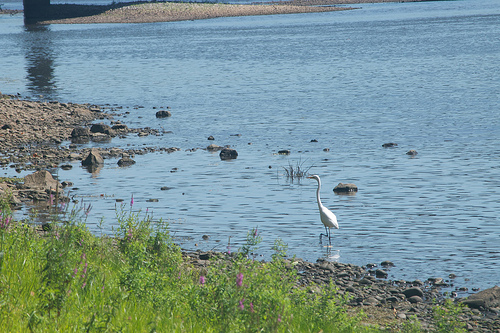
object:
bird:
[299, 174, 340, 244]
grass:
[2, 206, 467, 333]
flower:
[229, 269, 246, 289]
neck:
[316, 179, 323, 201]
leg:
[328, 227, 331, 239]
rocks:
[67, 124, 92, 145]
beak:
[305, 175, 314, 179]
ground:
[37, 0, 365, 26]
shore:
[321, 260, 434, 311]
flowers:
[194, 271, 210, 286]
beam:
[22, 21, 77, 31]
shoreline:
[12, 73, 274, 233]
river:
[0, 0, 500, 289]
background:
[193, 4, 459, 77]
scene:
[0, 0, 500, 333]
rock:
[369, 268, 389, 278]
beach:
[0, 76, 190, 209]